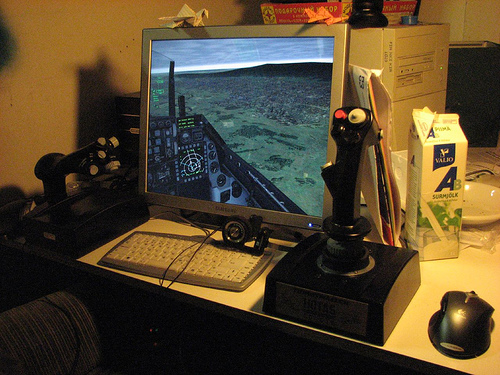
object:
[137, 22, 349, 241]
computer monitor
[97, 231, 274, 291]
keyboard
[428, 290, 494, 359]
mouse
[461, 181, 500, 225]
plate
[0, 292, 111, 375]
chair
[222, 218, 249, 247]
webcam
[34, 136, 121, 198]
joystick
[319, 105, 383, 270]
game controller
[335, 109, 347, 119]
button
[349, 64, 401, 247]
paper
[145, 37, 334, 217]
2. screen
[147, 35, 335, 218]
2. cartoons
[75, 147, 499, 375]
2. desk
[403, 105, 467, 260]
2. container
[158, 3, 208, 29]
2. swan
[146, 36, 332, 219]
2. game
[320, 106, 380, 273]
2. handle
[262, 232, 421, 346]
2. base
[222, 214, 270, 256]
2. headphones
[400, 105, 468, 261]
2. carton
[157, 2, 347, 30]
2. designs